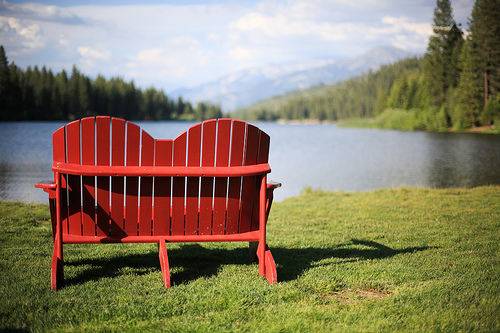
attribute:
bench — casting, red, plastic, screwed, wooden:
[29, 107, 293, 296]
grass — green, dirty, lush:
[3, 198, 499, 328]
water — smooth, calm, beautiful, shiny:
[2, 120, 500, 195]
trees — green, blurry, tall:
[3, 30, 500, 125]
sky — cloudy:
[6, 1, 454, 85]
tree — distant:
[184, 89, 233, 121]